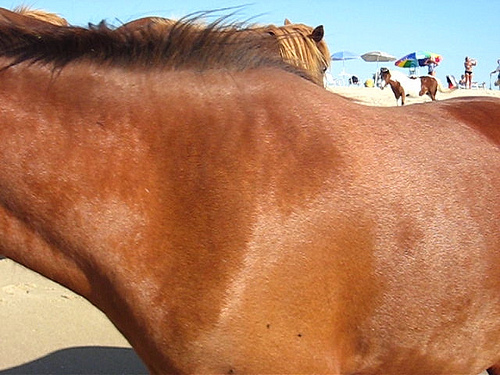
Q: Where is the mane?
A: On the brown horse.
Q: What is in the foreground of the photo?
A: Flank of a brown horse.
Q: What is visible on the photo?
A: A horse.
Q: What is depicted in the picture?
A: A horse.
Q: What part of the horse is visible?
A: A flank.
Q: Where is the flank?
A: On a visible brown horse.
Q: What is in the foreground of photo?
A: Horse with chestnut coloring.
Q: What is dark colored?
A: Mane on the horse.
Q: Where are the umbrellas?
A: In background.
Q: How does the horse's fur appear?
A: Shiny.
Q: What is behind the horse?
A: A beach.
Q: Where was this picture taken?
A: The beach.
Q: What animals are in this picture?
A: Horses.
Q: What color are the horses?
A: Brown and white.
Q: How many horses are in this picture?
A: Three.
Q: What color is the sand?
A: Tan.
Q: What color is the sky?
A: Blue.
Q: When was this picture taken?
A: During the day.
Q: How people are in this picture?
A: Two.